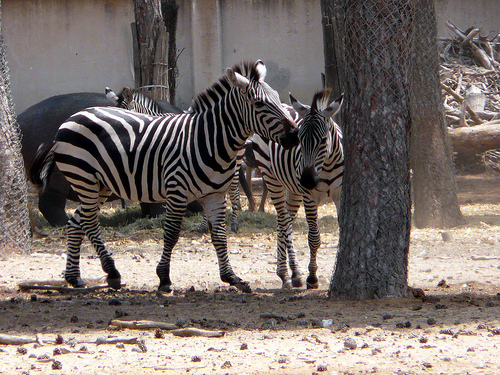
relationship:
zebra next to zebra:
[37, 59, 300, 298] [228, 82, 356, 295]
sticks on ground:
[108, 317, 225, 340] [4, 176, 499, 374]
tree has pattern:
[325, 2, 416, 299] [323, 0, 416, 300]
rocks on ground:
[20, 282, 488, 371] [4, 176, 499, 374]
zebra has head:
[102, 85, 170, 118] [101, 83, 164, 113]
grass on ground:
[25, 188, 315, 245] [4, 176, 499, 374]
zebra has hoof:
[37, 59, 300, 298] [155, 261, 173, 297]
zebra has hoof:
[37, 59, 300, 298] [218, 269, 249, 294]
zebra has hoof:
[37, 59, 300, 298] [62, 271, 87, 290]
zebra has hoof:
[37, 59, 300, 298] [102, 267, 124, 292]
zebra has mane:
[37, 59, 300, 298] [183, 58, 253, 118]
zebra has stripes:
[37, 59, 300, 298] [56, 107, 245, 192]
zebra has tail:
[37, 59, 300, 298] [27, 138, 57, 194]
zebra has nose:
[37, 59, 300, 298] [281, 124, 301, 144]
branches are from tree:
[108, 317, 225, 340] [325, 2, 416, 299]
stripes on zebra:
[56, 107, 245, 192] [37, 59, 300, 298]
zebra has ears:
[37, 59, 300, 298] [225, 58, 266, 89]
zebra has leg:
[102, 85, 170, 118] [228, 171, 241, 233]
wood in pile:
[436, 22, 497, 123] [437, 23, 499, 170]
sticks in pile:
[437, 24, 496, 128] [437, 23, 499, 170]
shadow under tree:
[1, 291, 498, 330] [325, 2, 416, 299]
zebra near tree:
[37, 59, 305, 298] [325, 2, 416, 299]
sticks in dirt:
[108, 317, 225, 340] [4, 176, 499, 374]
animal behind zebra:
[14, 91, 179, 217] [37, 59, 305, 298]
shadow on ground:
[1, 291, 498, 330] [4, 176, 499, 374]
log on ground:
[445, 122, 499, 152] [4, 176, 499, 374]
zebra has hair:
[37, 59, 300, 298] [183, 58, 253, 118]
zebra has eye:
[37, 59, 300, 298] [251, 99, 265, 111]